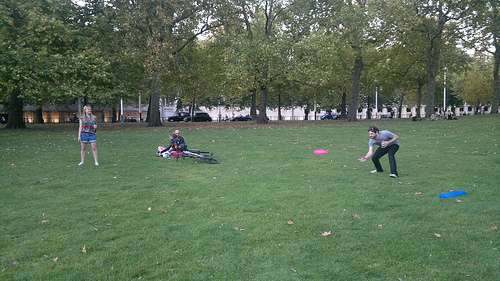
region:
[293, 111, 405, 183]
man catching a frisbee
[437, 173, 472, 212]
frisbee in the air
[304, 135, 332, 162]
frisbee in the air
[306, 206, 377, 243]
leaves on the ground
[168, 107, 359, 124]
vehicles on the street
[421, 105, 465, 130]
people on the lawn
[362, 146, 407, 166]
pants on the man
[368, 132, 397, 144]
shirt on the man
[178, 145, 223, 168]
bike on the ground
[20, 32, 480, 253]
The people are in a park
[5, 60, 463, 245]
Some people are playing a game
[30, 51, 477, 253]
Some people are standing in the grass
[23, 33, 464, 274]
A person is catching a frisbee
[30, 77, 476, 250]
Some frisbees are flying in the air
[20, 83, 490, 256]
Some people are on their day off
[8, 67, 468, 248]
Some people are out in the daytime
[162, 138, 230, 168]
this is a bike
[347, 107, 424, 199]
he is holding a drink in his band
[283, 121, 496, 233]
there are two flying discs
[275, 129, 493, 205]
there are two frisbees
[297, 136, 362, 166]
this frisbee is pink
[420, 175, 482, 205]
a blue flying disc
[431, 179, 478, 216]
this is a blue frisbee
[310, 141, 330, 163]
frisbee thrown in motion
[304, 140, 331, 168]
red frisbee in motion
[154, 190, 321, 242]
patch of green field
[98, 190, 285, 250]
patch of green grass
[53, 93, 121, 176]
young girl in field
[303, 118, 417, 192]
person catching a frisbee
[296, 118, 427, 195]
person catching a frisbee in grass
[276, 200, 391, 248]
some leaves and grass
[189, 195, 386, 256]
some leaves and green grass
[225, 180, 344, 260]
a big patch of green grass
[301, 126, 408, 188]
a guy playing with a frisbee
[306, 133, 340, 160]
a small and pink frisbee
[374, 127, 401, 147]
the left arm of a man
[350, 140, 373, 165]
the right arm of a man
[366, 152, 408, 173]
the legs of a man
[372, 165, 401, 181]
the shoes of a man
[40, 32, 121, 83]
a bunch of leaves on a tree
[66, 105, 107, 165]
a woman who is just standing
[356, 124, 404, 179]
man standing in big field wearing gray shirt and black pants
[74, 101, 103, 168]
blonde woman wearing light blue pants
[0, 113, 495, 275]
short green grass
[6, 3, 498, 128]
a bunch of trees in the background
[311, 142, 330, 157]
pink frisbee in the air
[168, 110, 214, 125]
black car parked in the background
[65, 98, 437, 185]
a group of people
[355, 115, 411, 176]
man is bending down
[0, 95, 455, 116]
a body of water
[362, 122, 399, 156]
man wearing a gray shirt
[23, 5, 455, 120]
a row of trees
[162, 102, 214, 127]
a pair of cars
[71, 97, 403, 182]
people are playing frisbee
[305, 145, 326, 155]
red frisbee is in the air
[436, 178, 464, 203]
blue frisbee is in the air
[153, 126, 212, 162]
kids are sitting on the ground by a bike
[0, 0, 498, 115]
tall trees around the park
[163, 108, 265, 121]
cars are parked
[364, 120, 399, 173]
man wearing long pants